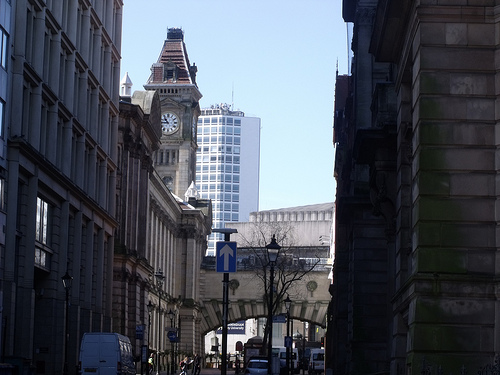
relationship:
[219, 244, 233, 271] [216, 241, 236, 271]
arrow on background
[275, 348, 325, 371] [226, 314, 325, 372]
traffic passing under archway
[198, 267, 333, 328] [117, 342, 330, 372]
bridge over street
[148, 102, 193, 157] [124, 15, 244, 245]
clock on building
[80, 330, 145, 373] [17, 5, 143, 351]
van parked near building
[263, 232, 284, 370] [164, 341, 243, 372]
lamp post on street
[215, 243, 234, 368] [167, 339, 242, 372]
pole on street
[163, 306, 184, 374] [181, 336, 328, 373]
lamp post on street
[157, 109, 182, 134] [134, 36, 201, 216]
clock on building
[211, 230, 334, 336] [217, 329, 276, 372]
overhang above vehicle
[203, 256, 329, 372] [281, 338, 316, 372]
cement above vehicle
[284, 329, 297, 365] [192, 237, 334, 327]
van under overhang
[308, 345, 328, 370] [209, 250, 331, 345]
van parked under overhang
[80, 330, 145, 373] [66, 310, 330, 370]
van driving down street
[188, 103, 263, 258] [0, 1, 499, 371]
building in city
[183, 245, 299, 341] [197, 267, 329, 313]
carving on bridge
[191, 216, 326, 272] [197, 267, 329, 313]
train on bridge